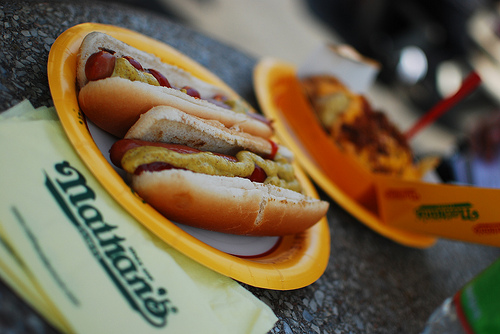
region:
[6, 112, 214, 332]
napkins on the table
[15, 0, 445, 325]
a table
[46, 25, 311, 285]
a paper plate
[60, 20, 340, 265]
two hot dogs on a paper plate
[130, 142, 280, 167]
mustard on the hot dog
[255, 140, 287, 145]
ketchup on the hot dog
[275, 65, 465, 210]
a box of food on a plate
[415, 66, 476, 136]
a fork in the food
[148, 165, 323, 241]
the hot dog bun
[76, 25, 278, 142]
hot dog with spicy brown mustard and ketchup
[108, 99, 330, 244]
hot dog with spicy brown mustard and ketchup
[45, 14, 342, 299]
white and yellow paper plate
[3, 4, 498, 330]
counter top made of small grey stones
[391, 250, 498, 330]
clear bottle with a red and green label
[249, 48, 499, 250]
chili cheese fries in a small yellow box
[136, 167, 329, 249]
edge of a crispy hot dog roll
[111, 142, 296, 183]
squiggly squirt of spicy brown mustard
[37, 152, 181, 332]
nathan's in green type face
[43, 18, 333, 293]
A plate is sitting on a table.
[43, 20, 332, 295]
The color of a plate is yellow.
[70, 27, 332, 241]
Two hot dog buns are sitting in a plate.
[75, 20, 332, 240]
the colors of two hot dog buns are brown and white.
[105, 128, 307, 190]
A frank is sitting in a hot dog bun.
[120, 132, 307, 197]
Mustard is on a frank.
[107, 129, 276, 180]
The color of a frank is red.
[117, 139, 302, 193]
The color of mustard on a frank is yellow.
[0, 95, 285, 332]
A napkin is sitting on a table.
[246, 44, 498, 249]
A second plate is sitting on a table.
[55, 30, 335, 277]
The hot dogs are on a plate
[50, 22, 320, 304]
The plate is made of paper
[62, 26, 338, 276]
The hot dogs are on buns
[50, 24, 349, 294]
There is mustard on the hot dogs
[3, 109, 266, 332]
There are Napkin's next to the plate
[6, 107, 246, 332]
The napkins say Nathan's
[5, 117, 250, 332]
The napkins are made of paper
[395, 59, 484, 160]
A red utensil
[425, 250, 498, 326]
A water bottle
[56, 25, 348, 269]
There are hot dogs on the plate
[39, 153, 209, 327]
"Nathan's" are on the napkin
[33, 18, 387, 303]
Plate is yellow and white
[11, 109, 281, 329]
Napkin is white and green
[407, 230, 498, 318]
A bottle on the table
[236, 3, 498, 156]
The background is blurry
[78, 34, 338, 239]
Condiments are ketchup and mustard